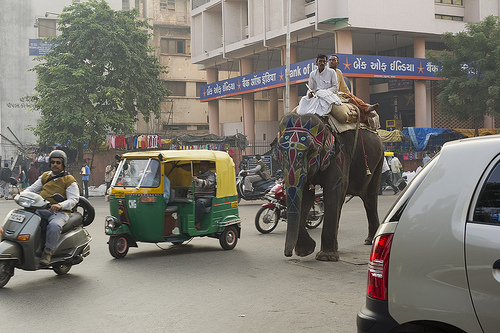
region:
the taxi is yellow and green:
[105, 145, 250, 276]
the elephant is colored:
[278, 129, 346, 199]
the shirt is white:
[308, 69, 338, 116]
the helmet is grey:
[48, 148, 75, 171]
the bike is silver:
[12, 206, 114, 268]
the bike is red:
[256, 182, 361, 254]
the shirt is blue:
[81, 166, 96, 180]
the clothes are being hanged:
[120, 124, 176, 151]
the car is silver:
[386, 148, 496, 331]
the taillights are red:
[362, 235, 404, 314]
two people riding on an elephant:
[257, 52, 382, 267]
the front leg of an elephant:
[315, 169, 347, 265]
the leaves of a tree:
[65, 33, 131, 105]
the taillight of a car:
[362, 228, 394, 313]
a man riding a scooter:
[4, 142, 97, 292]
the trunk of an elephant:
[277, 155, 308, 266]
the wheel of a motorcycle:
[254, 202, 281, 235]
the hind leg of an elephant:
[364, 169, 381, 247]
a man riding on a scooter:
[233, 148, 276, 205]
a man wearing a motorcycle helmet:
[41, 144, 71, 178]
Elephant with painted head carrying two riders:
[271, 51, 391, 268]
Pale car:
[352, 130, 497, 329]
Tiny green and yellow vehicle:
[96, 146, 246, 258]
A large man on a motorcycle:
[0, 144, 98, 290]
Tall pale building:
[184, 0, 498, 175]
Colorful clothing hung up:
[46, 126, 240, 149]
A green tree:
[25, 2, 170, 201]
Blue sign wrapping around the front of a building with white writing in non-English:
[190, 51, 482, 108]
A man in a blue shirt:
[75, 157, 92, 198]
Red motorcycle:
[251, 174, 335, 244]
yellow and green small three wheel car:
[104, 143, 244, 262]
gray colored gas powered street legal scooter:
[1, 190, 98, 292]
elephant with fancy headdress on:
[273, 106, 390, 265]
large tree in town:
[24, 0, 179, 200]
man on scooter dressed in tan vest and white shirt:
[13, 145, 75, 268]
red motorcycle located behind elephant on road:
[253, 172, 323, 237]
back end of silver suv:
[352, 126, 498, 331]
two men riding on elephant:
[292, 48, 386, 142]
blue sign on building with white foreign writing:
[193, 49, 482, 107]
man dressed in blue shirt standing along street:
[76, 157, 98, 199]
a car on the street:
[46, 106, 406, 318]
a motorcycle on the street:
[19, 113, 121, 330]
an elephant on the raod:
[237, 33, 461, 331]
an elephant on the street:
[222, 28, 494, 293]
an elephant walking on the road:
[254, 73, 403, 243]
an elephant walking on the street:
[216, 61, 457, 318]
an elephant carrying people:
[267, 33, 381, 237]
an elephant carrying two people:
[248, 33, 437, 274]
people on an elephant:
[249, 47, 415, 299]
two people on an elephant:
[229, 31, 436, 330]